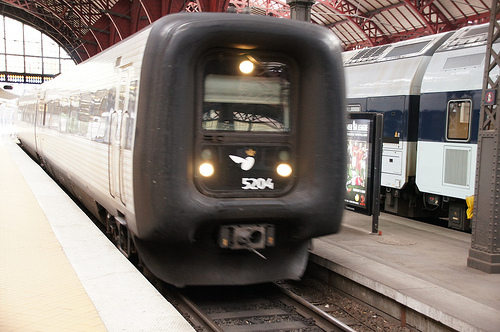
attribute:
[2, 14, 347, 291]
train — square, black, long, silver, white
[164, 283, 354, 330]
tracks — metal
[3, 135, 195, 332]
platform — paved, cement, white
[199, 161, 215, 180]
light — glowing, on, bright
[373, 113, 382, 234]
post — black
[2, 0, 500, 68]
roof — curved, red, ribbed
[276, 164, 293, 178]
light — bright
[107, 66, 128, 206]
door — closed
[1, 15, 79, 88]
window — arched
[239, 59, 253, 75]
light — circular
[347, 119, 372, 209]
poster — colorful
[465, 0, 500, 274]
support beam — gray